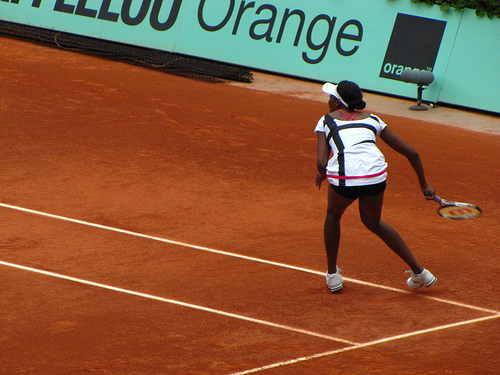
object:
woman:
[312, 80, 441, 293]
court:
[0, 33, 500, 375]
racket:
[425, 192, 483, 220]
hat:
[322, 82, 349, 108]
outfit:
[313, 112, 389, 199]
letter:
[335, 18, 362, 57]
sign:
[377, 11, 450, 88]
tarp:
[0, 19, 255, 85]